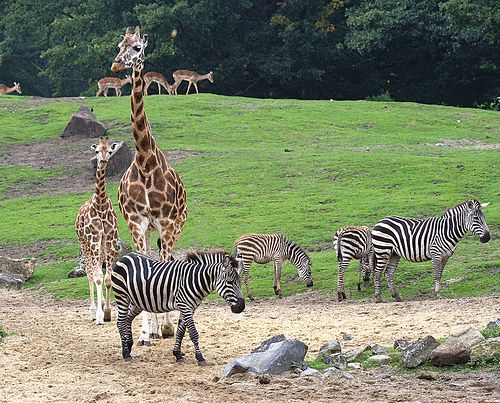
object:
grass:
[291, 326, 499, 375]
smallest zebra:
[233, 233, 314, 301]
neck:
[128, 68, 157, 155]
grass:
[0, 90, 498, 302]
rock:
[61, 101, 107, 140]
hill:
[0, 92, 498, 303]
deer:
[143, 68, 171, 94]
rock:
[90, 141, 134, 176]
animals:
[77, 20, 491, 364]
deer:
[96, 75, 133, 97]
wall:
[300, 119, 368, 171]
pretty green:
[3, 78, 498, 295]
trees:
[1, 0, 500, 98]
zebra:
[371, 197, 493, 303]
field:
[1, 91, 497, 302]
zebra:
[109, 247, 246, 367]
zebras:
[108, 197, 490, 365]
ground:
[0, 93, 497, 401]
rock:
[223, 337, 307, 377]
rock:
[429, 336, 470, 366]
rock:
[469, 336, 499, 366]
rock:
[401, 335, 440, 369]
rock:
[367, 355, 393, 366]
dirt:
[3, 285, 495, 400]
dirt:
[0, 300, 498, 403]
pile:
[221, 317, 498, 381]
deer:
[172, 70, 214, 96]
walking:
[111, 248, 245, 366]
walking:
[371, 197, 492, 303]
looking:
[94, 147, 115, 156]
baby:
[73, 135, 119, 325]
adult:
[109, 23, 186, 346]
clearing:
[4, 95, 496, 399]